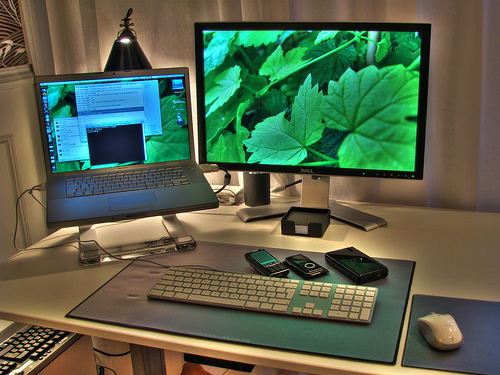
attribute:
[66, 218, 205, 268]
computer stand — gray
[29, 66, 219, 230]
laptop computer — gray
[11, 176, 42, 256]
cord — white, computer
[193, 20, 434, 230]
monitor — desktop, computer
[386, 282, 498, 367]
pad — black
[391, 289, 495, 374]
mouse — white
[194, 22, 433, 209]
monitor — large, on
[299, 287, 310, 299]
key — plastic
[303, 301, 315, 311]
key — plastic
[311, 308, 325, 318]
key — plastic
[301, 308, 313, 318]
key — plastic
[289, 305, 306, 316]
key — plastic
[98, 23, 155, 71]
lamp — desk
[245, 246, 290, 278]
cellphone — black, small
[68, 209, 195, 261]
platform — raised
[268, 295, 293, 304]
key — white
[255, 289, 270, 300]
key — white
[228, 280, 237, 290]
key — white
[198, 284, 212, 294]
key — white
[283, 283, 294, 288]
key — white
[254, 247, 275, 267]
screen — green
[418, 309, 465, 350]
mouse — white